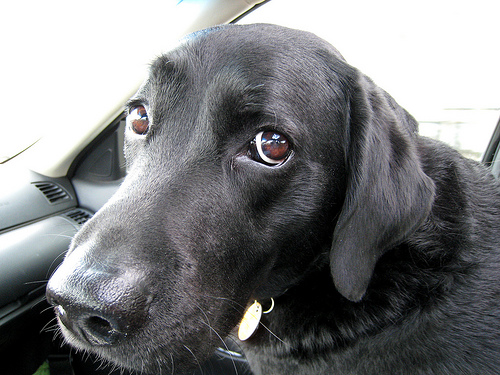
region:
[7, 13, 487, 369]
Dog is inside car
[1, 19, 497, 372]
Dog is looking at the camera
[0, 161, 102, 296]
Dashboard with ac duct of the car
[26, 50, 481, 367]
Black color dog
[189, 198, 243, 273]
Cheek of the dog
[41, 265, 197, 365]
Mouth and nose of the dog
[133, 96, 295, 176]
Eyes of the dog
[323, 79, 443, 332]
Ear of the dog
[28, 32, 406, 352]
Face of the dog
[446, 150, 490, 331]
Black color hair of the dog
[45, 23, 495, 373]
A large black dog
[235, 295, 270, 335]
tags on the dog's collar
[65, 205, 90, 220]
an air conditioning vent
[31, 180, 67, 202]
an air conditioning vent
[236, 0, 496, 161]
A car window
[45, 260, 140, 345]
The large wet nose of the dog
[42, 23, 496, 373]
A dog in a car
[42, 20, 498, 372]
A black Labrador dog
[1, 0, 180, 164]
the windshield of a car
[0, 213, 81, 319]
A glove box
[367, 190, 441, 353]
dog has black fur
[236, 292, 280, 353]
dog has a tag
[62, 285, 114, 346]
dog's nose is black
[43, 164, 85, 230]
vents in the vehicle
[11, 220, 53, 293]
dashboard of the vehicle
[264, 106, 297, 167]
dog's eyes are brown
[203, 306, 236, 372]
dog's whiskers are white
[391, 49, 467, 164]
dog seating in vehicle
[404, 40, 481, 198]
dog is next to the window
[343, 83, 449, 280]
dog's ears are down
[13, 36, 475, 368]
Inside a vehicle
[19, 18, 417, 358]
a black dog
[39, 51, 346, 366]
the dog is looking at the camera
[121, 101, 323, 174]
the dog has brown eyes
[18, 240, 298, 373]
the dog has whiskers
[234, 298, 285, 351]
the dog has a silver tag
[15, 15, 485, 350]
the dog is in the passenger seat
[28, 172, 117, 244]
the air vents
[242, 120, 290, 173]
the dog has white parts of the eyes showing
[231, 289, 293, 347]
A dog has a tag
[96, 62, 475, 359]
this is a dog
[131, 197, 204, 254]
the dog is black in color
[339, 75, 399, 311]
this is the ear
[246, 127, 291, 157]
this is the eye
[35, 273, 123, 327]
this is the nose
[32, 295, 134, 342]
the nose is wet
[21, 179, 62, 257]
this is a car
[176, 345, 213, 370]
this is a fur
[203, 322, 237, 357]
the fur is white in color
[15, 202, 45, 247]
this is the dash board